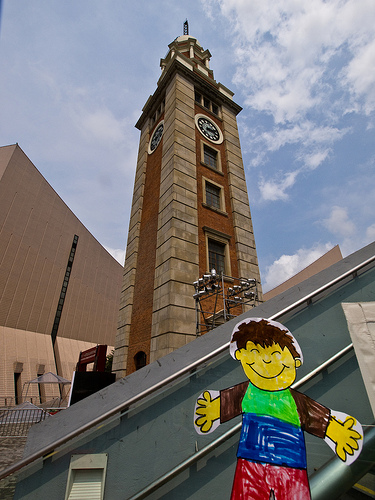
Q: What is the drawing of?
A: Flat Stanley.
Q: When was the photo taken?
A: In the daytime.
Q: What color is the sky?
A: Blue.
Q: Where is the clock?
A: On the building.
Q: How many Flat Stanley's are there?
A: One.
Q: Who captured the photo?
A: A photographer.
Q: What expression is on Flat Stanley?
A: A smile.